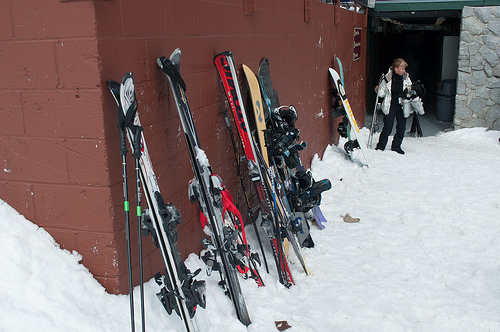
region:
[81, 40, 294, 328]
Skis against the building.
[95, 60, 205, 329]
Black and white skis.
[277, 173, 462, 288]
Snow on the ground.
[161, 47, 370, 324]
Skis against the brick wall.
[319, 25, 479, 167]
Woman in the background.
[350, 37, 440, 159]
Woman holding her skis.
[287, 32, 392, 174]
Skis in the background.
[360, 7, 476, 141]
Opening to a building.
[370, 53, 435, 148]
Woman in a coat.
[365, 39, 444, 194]
Woman in a white coat.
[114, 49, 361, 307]
skis leaning against building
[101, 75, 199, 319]
two white skis near wall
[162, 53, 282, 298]
two black skis on wall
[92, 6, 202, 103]
wall is red brick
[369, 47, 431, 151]
woman is holding skis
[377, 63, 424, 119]
woman has white coat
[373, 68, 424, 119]
woman has black shirt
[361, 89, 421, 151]
woman has black pants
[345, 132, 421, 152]
woman has black shoes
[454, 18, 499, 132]
grey and rock wall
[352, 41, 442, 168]
an old woman on snow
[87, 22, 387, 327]
skis lean on wall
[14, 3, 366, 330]
skis leans on red wall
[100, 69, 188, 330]
black poles lean on skis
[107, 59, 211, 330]
skis color gray and black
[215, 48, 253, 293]
red skis leans on red wall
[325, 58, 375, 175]
a white surfboard leans on red wall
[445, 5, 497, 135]
a wall of stone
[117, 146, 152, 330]
black and green poles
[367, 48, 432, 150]
woman wears a black and white coat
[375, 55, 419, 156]
This is a person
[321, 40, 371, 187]
This is a scatting board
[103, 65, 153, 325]
This is a scatting board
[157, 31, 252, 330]
This is a scatting board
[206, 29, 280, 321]
This is a scatting board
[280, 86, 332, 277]
This is a scatting board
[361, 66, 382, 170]
This is a skiing pole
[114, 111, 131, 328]
This is a skiing pole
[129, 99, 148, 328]
This is a skiing pole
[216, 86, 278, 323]
This is a skiing pole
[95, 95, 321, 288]
These are skis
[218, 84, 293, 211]
The ski is red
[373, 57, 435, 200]
This is a woman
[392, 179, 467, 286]
These are footprints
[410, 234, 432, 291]
There is snow on the ground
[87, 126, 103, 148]
This is a concrete wall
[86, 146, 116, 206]
These are red bricks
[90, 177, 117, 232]
The wall is red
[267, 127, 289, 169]
This is a foot holder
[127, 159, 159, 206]
This is a pole